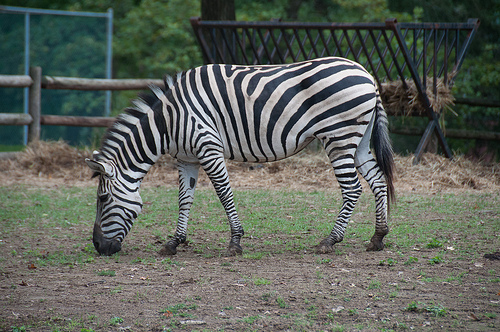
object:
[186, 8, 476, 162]
hay dispenser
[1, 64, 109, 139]
fence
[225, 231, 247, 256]
hoof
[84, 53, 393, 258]
zebra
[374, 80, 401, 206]
tail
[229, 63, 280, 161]
stripe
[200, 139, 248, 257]
leg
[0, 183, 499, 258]
grass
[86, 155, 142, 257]
head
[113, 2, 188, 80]
bush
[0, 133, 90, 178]
pile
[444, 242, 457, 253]
leaf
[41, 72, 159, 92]
pole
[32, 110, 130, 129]
pole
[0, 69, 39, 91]
pole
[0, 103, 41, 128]
pole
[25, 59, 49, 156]
pole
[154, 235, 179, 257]
hoof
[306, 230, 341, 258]
hoof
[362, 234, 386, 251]
hoof